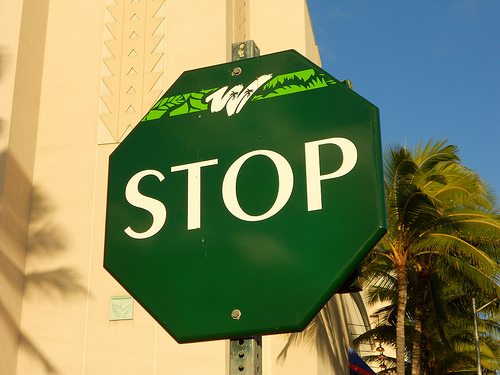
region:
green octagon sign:
[66, 40, 407, 357]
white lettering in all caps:
[113, 129, 364, 257]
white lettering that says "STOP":
[116, 135, 363, 238]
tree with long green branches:
[371, 143, 498, 373]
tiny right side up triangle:
[124, 45, 139, 60]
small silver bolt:
[219, 298, 247, 328]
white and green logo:
[131, 63, 341, 118]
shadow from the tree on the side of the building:
[1, 123, 103, 370]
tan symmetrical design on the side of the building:
[102, 1, 159, 143]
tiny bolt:
[229, 65, 242, 77]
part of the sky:
[418, 28, 482, 90]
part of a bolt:
[221, 297, 233, 319]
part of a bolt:
[248, 231, 288, 276]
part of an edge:
[275, 306, 310, 343]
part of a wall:
[26, 307, 81, 363]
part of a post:
[233, 342, 257, 372]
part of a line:
[76, 297, 126, 334]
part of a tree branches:
[441, 240, 494, 282]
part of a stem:
[383, 300, 408, 337]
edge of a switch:
[98, 306, 123, 329]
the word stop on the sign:
[113, 138, 350, 231]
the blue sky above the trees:
[310, 4, 499, 144]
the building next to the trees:
[5, 0, 367, 371]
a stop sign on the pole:
[99, 53, 394, 342]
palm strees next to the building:
[384, 145, 497, 374]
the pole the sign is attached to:
[216, 329, 268, 374]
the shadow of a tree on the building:
[0, 172, 78, 367]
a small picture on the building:
[107, 292, 137, 323]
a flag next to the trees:
[344, 345, 375, 370]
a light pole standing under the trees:
[461, 283, 494, 371]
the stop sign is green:
[62, 24, 420, 348]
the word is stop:
[96, 26, 438, 358]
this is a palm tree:
[386, 107, 496, 287]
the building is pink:
[32, 89, 87, 178]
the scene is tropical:
[51, 17, 469, 362]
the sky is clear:
[381, 32, 491, 110]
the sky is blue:
[431, 102, 498, 127]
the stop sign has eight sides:
[73, 36, 452, 357]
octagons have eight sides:
[70, 20, 430, 367]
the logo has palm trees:
[61, 18, 431, 352]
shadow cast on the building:
[18, 165, 94, 269]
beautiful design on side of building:
[82, 20, 192, 47]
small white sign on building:
[88, 288, 150, 330]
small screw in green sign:
[209, 295, 267, 335]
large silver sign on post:
[208, 335, 293, 363]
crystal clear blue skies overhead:
[390, 35, 499, 92]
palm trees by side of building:
[393, 143, 483, 282]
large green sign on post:
[89, 46, 427, 300]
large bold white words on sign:
[131, 143, 370, 246]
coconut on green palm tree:
[395, 252, 441, 282]